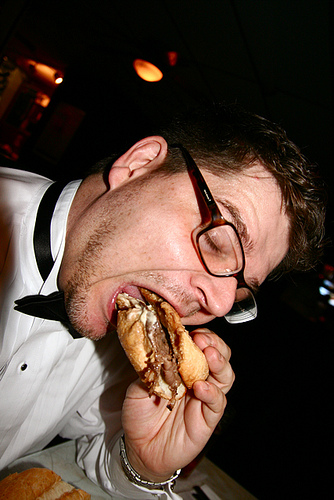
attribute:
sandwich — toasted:
[111, 276, 223, 414]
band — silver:
[119, 407, 193, 499]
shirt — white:
[11, 150, 180, 496]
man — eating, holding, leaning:
[90, 116, 275, 394]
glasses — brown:
[173, 155, 274, 349]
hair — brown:
[177, 105, 315, 259]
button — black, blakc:
[11, 349, 55, 378]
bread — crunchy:
[144, 274, 227, 390]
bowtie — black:
[29, 180, 94, 359]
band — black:
[31, 173, 60, 344]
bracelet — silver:
[104, 432, 194, 494]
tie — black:
[32, 184, 75, 363]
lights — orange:
[44, 16, 219, 137]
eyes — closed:
[197, 216, 242, 312]